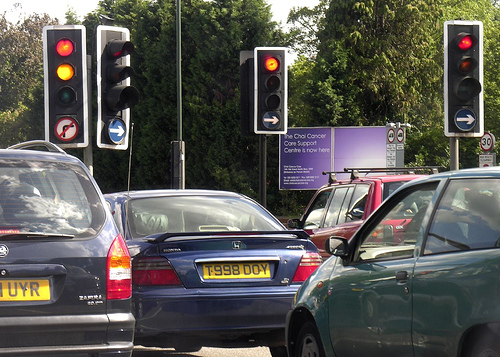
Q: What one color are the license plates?
A: Yellow.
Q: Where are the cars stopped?
A: At the light.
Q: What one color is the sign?
A: Blue.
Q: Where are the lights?
A: On the traffic lights.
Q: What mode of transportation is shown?
A: Vehicles.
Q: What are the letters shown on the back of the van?
A: UYR.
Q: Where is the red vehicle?
A: Far right front.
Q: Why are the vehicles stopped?
A: Red signal light.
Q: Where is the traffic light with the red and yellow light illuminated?
A: Light on the left.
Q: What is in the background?
A: Trees.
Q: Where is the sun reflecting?
A: Vehicle windows.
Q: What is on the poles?
A: Traffic signals.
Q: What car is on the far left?
A: Blue minivan.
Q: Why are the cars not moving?
A: Traffic light is red.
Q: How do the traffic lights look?
A: Jumbled.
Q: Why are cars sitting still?
A: Red light.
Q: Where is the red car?
A: Next to the blue.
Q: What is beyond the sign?
A: Trees.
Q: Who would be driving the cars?
A: People.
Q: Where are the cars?
A: Traffic stop.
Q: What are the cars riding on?
A: The road.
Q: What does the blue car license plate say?
A: T998doy.